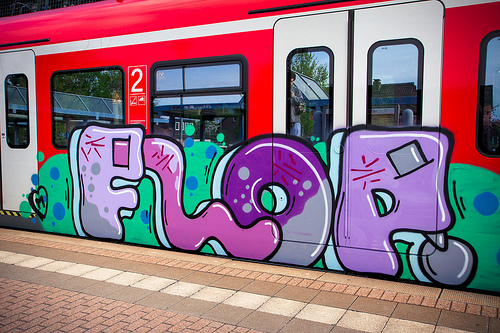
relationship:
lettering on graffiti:
[268, 184, 338, 271] [62, 115, 478, 296]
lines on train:
[0, 33, 56, 49] [0, 0, 500, 295]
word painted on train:
[65, 116, 456, 290] [0, 0, 500, 295]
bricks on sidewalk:
[117, 294, 167, 329] [41, 249, 180, 317]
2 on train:
[124, 60, 152, 101] [3, 15, 453, 257]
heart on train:
[17, 175, 61, 230] [17, 21, 477, 314]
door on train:
[271, 0, 442, 286] [0, 0, 500, 295]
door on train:
[344, 0, 441, 256] [0, 0, 500, 295]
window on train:
[474, 30, 498, 156] [0, 0, 500, 295]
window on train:
[369, 41, 422, 128] [0, 0, 500, 295]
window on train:
[287, 49, 327, 167] [0, 0, 500, 295]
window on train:
[151, 60, 249, 149] [0, 0, 500, 295]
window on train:
[50, 69, 123, 148] [0, 0, 500, 295]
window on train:
[5, 73, 31, 149] [0, 0, 500, 295]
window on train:
[474, 30, 498, 152] [0, 0, 500, 295]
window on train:
[151, 60, 249, 156] [0, 0, 500, 295]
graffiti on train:
[17, 123, 498, 293] [0, 0, 500, 295]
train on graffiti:
[0, 0, 500, 295] [17, 123, 498, 293]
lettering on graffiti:
[77, 120, 480, 290] [17, 123, 498, 293]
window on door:
[369, 41, 422, 128] [344, 0, 441, 256]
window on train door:
[287, 49, 330, 167] [271, 8, 351, 248]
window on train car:
[474, 30, 498, 156] [3, 0, 498, 296]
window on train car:
[151, 60, 249, 149] [3, 0, 498, 296]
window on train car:
[50, 69, 123, 148] [3, 0, 498, 296]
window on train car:
[1, 73, 28, 147] [3, 0, 498, 296]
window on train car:
[369, 41, 422, 128] [3, 0, 498, 296]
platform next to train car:
[0, 229, 499, 329] [3, 0, 498, 296]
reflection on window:
[481, 76, 499, 153] [478, 32, 498, 158]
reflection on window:
[365, 41, 419, 130] [369, 41, 422, 128]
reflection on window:
[287, 47, 333, 147] [289, 50, 330, 145]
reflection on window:
[153, 60, 247, 150] [151, 60, 249, 149]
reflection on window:
[47, 69, 120, 149] [50, 69, 123, 148]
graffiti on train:
[332, 128, 454, 276] [0, 0, 500, 295]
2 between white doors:
[130, 68, 144, 93] [1, 1, 451, 250]